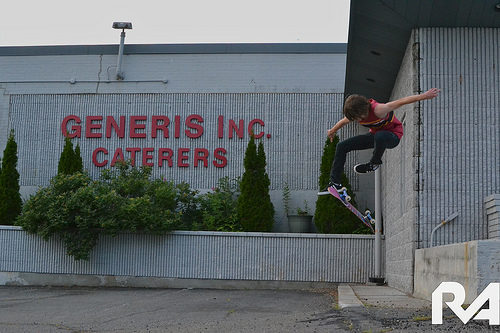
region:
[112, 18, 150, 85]
a white security camera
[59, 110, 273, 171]
red letters on the side of a building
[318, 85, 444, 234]
a guy on a skate board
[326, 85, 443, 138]
a guy with a red shirt with colored strips on it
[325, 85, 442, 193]
a guy wearing jeans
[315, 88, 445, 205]
a guy wearing black and white shoes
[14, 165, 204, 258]
bushes with flowers on it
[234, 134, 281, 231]
green tree in front of a building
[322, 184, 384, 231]
a pink skate board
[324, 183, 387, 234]
a skate board with white wheels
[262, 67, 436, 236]
a boy skateboarding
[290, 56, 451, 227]
a boy flipping a skateboard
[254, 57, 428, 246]
a boy skateboarding outside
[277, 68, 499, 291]
a boy flipping a skateboard outside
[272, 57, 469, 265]
a boy doing a trick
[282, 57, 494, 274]
a boy doing a stunt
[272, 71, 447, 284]
a boy doing a skateboard trick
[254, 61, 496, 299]
a boy doing a skateboard stunt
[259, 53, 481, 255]
a boy wearing a shirt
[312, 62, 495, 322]
a boy wearing pants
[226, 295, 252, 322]
part of a floor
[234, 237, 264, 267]
part of a fence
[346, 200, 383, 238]
part of a wheel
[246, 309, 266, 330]
part of a floor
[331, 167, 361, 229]
part of a board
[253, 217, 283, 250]
part of a fence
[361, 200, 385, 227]
part of a wheel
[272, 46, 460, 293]
a boy on a skateboard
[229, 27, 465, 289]
a boy in the air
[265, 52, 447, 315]
a skateboarder in the air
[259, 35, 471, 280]
a young boy in the air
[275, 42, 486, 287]
a young boy on a skateboard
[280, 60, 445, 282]
a skateboarder doing a trick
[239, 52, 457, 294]
a skateboarder doing a stunt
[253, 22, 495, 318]
a skateboarder flipping skateboard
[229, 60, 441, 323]
a boy flipping skateboard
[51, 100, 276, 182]
red letters on the side of the building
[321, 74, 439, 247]
skateboarder in mid air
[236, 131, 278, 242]
small green trees in planter against building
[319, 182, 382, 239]
pink and blue skateboard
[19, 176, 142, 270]
bush growing over planter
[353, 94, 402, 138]
skateboarder wearing a red shirt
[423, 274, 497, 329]
white RA in the corner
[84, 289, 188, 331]
grey pavement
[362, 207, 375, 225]
white wheels on the skateboard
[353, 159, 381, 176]
black tennis shoe